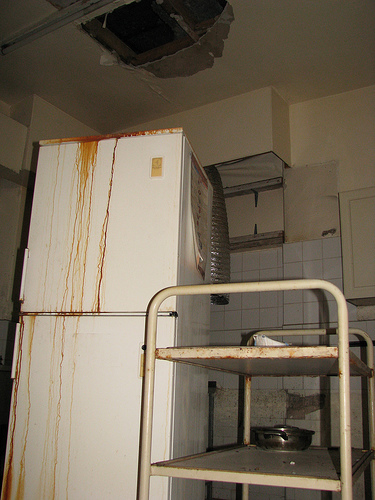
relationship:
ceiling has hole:
[3, 0, 374, 125] [69, 1, 214, 57]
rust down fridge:
[72, 138, 101, 216] [3, 126, 213, 499]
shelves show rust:
[139, 278, 373, 492] [224, 351, 242, 365]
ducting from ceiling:
[200, 166, 242, 307] [3, 0, 374, 125]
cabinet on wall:
[326, 186, 374, 306] [241, 238, 345, 278]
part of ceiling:
[316, 64, 321, 72] [3, 0, 374, 125]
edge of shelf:
[171, 347, 181, 350] [159, 342, 369, 380]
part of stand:
[175, 468, 177, 469] [139, 278, 373, 492]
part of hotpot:
[272, 439, 275, 442] [245, 419, 317, 453]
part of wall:
[349, 119, 356, 132] [289, 102, 374, 181]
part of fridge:
[122, 211, 125, 217] [3, 126, 213, 499]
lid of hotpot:
[254, 423, 315, 435] [245, 419, 317, 453]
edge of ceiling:
[325, 91, 333, 94] [3, 0, 374, 125]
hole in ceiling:
[69, 1, 214, 57] [3, 0, 374, 125]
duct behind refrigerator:
[200, 166, 242, 307] [3, 126, 213, 499]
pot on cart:
[245, 419, 317, 453] [139, 278, 373, 492]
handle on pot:
[256, 425, 288, 441] [245, 419, 317, 453]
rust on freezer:
[72, 138, 101, 216] [32, 134, 214, 315]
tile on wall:
[305, 238, 322, 261] [241, 238, 345, 278]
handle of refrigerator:
[9, 321, 28, 381] [24, 128, 229, 499]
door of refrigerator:
[15, 309, 172, 497] [24, 128, 229, 499]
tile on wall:
[301, 261, 324, 279] [241, 238, 345, 278]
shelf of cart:
[159, 342, 369, 380] [139, 278, 373, 492]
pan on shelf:
[245, 419, 317, 453] [144, 438, 354, 493]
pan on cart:
[245, 419, 317, 453] [139, 278, 373, 492]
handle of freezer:
[18, 244, 33, 305] [32, 134, 214, 315]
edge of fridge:
[124, 132, 138, 136] [3, 126, 213, 499]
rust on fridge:
[72, 138, 101, 216] [3, 126, 213, 499]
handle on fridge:
[9, 321, 28, 381] [3, 126, 213, 499]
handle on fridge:
[18, 244, 33, 305] [3, 126, 213, 499]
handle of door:
[9, 321, 28, 381] [15, 309, 172, 497]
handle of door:
[18, 244, 33, 305] [30, 136, 181, 303]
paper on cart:
[252, 334, 295, 348] [139, 278, 373, 492]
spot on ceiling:
[104, 53, 117, 70] [3, 0, 374, 125]